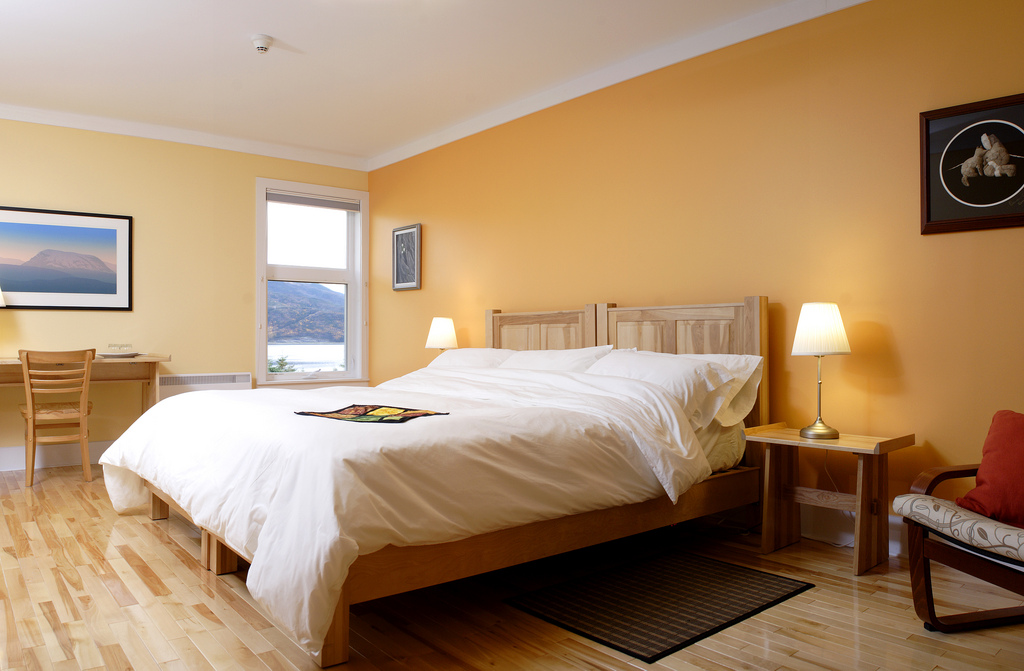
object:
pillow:
[497, 331, 624, 385]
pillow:
[417, 334, 519, 388]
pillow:
[581, 334, 762, 421]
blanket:
[94, 349, 730, 656]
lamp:
[781, 280, 881, 449]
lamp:
[405, 297, 479, 363]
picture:
[902, 84, 1022, 246]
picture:
[381, 218, 428, 296]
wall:
[356, 0, 1020, 484]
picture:
[0, 189, 142, 319]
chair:
[880, 380, 1023, 659]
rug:
[478, 524, 841, 670]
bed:
[88, 290, 834, 667]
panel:
[600, 306, 680, 346]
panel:
[619, 318, 740, 351]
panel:
[611, 318, 661, 351]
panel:
[695, 318, 738, 357]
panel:
[635, 319, 659, 343]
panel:
[621, 322, 640, 339]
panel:
[540, 325, 567, 344]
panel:
[677, 323, 701, 352]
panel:
[539, 323, 553, 340]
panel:
[517, 323, 536, 343]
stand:
[727, 401, 922, 586]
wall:
[0, 112, 379, 443]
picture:
[383, 217, 434, 300]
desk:
[0, 332, 173, 461]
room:
[0, 0, 1019, 668]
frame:
[79, 379, 794, 667]